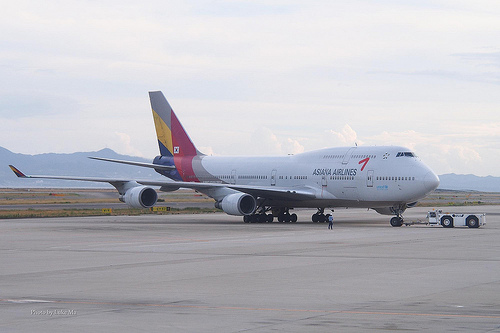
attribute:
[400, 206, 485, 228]
truck — White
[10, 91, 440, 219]
plane — large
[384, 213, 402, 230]
wheel — Black, In front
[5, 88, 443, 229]
plane — Large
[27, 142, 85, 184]
mountain — Large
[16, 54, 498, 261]
plane — On wheels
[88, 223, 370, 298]
tarmac — expanse, gray